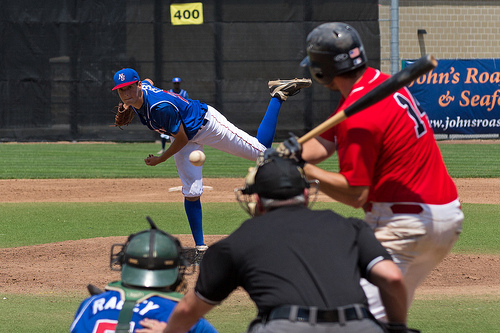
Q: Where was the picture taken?
A: On a baseball field.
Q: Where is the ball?
A: In the air.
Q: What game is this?
A: Baseball.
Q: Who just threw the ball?
A: The pitcher.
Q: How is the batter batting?
A: Lefty.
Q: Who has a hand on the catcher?
A: The umpire.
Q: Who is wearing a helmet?
A: The batter and the catcher.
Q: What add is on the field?
A: John's Roof & Seal.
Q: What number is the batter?
A: 14.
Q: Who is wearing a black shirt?
A: The umpire.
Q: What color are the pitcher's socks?
A: Blue.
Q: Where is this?
A: Baseball field.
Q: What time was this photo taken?
A: It was taken during the day.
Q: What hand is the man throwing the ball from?
A: Left.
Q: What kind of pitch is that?
A: Spinning.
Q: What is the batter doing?
A: Swinging the ball.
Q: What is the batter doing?
A: Opening hips.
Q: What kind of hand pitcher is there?
A: Lanky left.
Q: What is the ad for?
A: Seafood restaurant.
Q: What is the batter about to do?
A: Uncoil.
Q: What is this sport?
A: Baseball.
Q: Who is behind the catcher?
A: An umpire.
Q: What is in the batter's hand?
A: A bat.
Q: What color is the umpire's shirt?
A: Black.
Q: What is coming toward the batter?
A: A baseball.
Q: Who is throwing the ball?
A: A pitcher.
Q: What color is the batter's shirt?
A: Red.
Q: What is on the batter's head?
A: A helmet.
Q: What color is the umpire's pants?
A: Gray.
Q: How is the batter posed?
A: Ready to swing.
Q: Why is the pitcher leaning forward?
A: Just threw the ball.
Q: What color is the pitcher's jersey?
A: Blue.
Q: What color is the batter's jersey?
A: Red.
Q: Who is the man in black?
A: Umpire.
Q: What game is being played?
A: Baseball.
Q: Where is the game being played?
A: Baseball field.